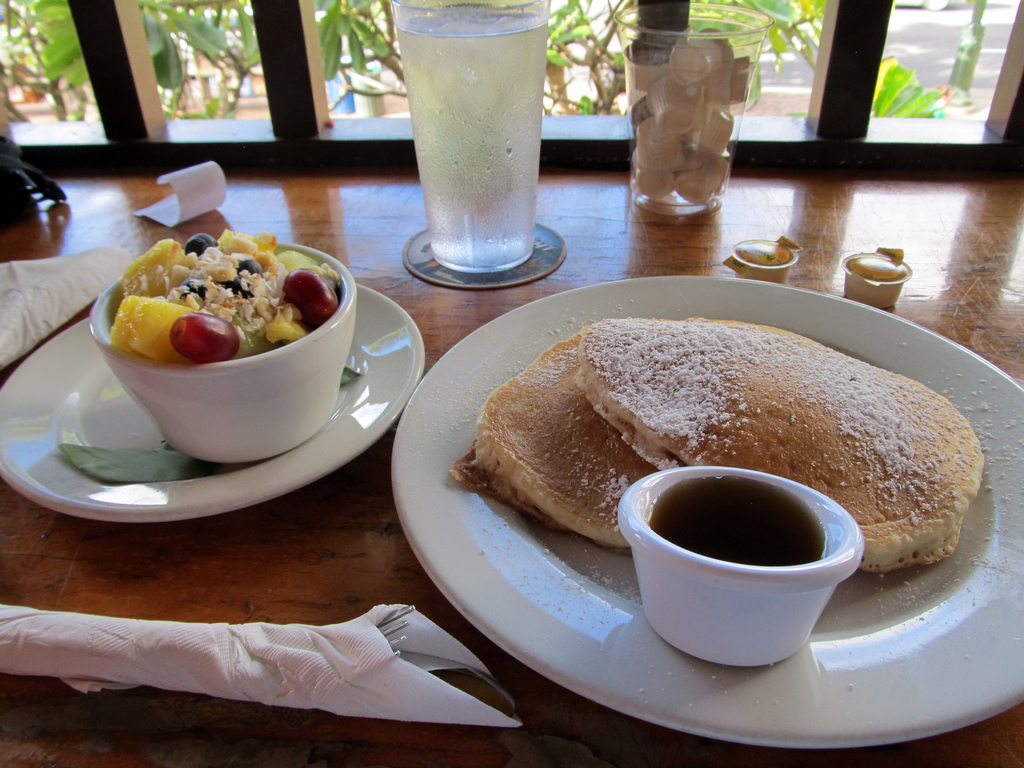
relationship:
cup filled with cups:
[637, 10, 728, 201] [639, 58, 724, 169]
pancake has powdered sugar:
[464, 234, 1002, 621] [587, 303, 855, 470]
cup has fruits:
[88, 232, 365, 466] [77, 190, 328, 353]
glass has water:
[414, 41, 548, 303] [410, 55, 544, 267]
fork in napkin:
[0, 601, 422, 688] [0, 602, 528, 735]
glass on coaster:
[386, 1, 555, 269] [395, 220, 566, 283]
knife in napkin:
[17, 602, 527, 736] [12, 602, 518, 734]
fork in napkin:
[6, 591, 516, 728] [12, 602, 518, 734]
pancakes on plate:
[464, 306, 989, 587] [391, 269, 1003, 747]